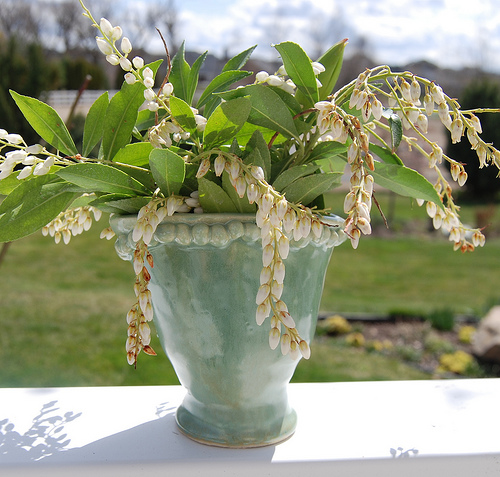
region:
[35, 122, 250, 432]
Flowers in a vase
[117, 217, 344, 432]
Colorful clay vase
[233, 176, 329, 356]
Seed pods growing together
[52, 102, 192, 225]
Green bunch of leaves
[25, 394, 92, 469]
Shadow on the table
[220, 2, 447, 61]
Clouds in the sky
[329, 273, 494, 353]
Landscaping in the background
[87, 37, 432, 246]
Flowers filling the vase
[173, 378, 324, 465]
Base of the vase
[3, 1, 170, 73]
Tree without leaves in background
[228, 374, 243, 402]
the vase is green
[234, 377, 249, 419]
the vase is green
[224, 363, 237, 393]
the vase is green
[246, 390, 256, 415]
the vase is green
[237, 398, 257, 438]
the vase is green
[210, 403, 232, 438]
the vase is green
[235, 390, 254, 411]
the vase is green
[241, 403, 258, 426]
the vase is green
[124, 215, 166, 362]
wilting white flowers in white vase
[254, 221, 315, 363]
wilting white flowers in white vase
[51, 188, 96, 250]
wilting white flowers in white vase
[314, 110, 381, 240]
wilting white flowers in white vase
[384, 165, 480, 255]
wilting white flowers in white vase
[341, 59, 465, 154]
wilting white flowers in white vase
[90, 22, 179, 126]
wilting white flowers in white vase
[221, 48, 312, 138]
wilting white flowers in white vase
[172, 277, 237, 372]
wilting white flowers in white vase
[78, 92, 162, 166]
green leaves of wilting white flowers in white vase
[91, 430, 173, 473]
shadow of the blue vase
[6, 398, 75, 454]
shadow of the flowers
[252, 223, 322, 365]
white flowers of the plant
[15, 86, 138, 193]
leaves of the flower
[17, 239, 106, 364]
the green grass of the yard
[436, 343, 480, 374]
yellow flowers in the garden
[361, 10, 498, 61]
clouds in the sky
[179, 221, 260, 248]
decorative trim on the vase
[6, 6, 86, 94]
The trees wth no leaves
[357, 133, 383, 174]
dead flowers of the plant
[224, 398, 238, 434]
the vase is green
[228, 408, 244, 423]
the vase is green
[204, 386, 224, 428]
the vase is green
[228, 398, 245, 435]
the vase is green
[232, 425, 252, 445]
the vase is green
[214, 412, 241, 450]
the vase is green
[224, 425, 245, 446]
the vase is green